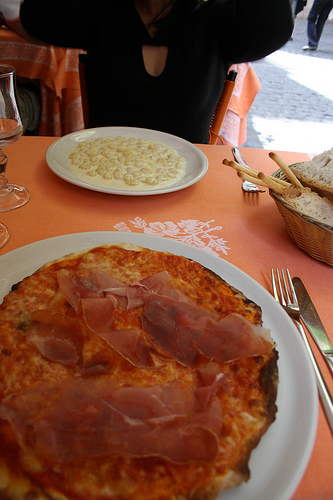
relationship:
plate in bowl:
[176, 133, 216, 186] [249, 293, 323, 413]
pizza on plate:
[52, 255, 261, 475] [176, 133, 216, 186]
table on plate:
[179, 194, 293, 268] [176, 133, 216, 186]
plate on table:
[176, 133, 216, 186] [179, 194, 293, 268]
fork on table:
[260, 251, 305, 298] [179, 194, 293, 268]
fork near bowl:
[260, 251, 305, 298] [249, 293, 323, 413]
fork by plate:
[260, 251, 305, 298] [176, 133, 216, 186]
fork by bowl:
[260, 251, 305, 298] [249, 293, 323, 413]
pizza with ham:
[52, 255, 261, 475] [78, 288, 241, 369]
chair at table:
[50, 29, 297, 152] [26, 215, 322, 425]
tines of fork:
[265, 253, 302, 312] [260, 251, 305, 298]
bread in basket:
[213, 130, 318, 209] [258, 129, 322, 239]